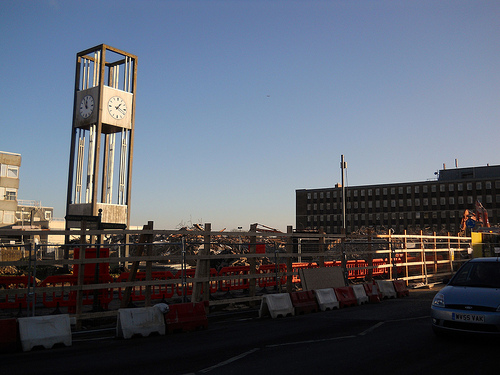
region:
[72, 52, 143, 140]
clock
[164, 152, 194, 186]
white clouds n blue sky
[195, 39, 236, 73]
white clouds n blue sky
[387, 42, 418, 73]
white clouds n blue sky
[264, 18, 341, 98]
white clouds n blue sky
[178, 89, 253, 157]
white clouds n blue sky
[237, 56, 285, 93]
white clouds n blue sky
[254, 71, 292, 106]
white clouds n blue sky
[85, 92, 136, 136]
clock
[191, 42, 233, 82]
white clouds in blue sky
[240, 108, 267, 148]
white clouds in blue sky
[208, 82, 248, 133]
white clouds in blue sky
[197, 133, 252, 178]
white clouds in blue sky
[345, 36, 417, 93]
white clouds in blue sky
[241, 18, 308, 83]
white clouds in blue sky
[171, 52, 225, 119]
white clouds in blue sky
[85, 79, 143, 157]
clock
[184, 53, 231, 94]
blue sky with no clouds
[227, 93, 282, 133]
blue sky with no clouds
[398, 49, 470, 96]
blue sky with no clouds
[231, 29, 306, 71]
blue sky with no clouds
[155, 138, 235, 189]
blue sky with no clouds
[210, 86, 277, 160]
blue sky with no clouds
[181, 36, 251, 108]
blue sky with no clouds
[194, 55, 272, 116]
blue sky with no clouds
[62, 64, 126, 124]
clock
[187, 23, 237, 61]
white clouds in blue sky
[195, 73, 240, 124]
white clouds in blue sky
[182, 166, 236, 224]
white clouds in blue sky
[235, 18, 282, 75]
white clouds in blue sky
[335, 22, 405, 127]
white clouds in blue sky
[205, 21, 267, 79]
white clouds in blue sky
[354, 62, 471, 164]
white clouds in blue sky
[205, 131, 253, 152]
white clouds in blue sky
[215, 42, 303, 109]
white clouds in blue sky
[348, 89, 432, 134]
white clouds in blue sky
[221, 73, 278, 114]
white clouds in blue sky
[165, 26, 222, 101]
white clouds in blue sky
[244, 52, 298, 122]
white clouds in blue sky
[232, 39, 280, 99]
white clouds in blue sky